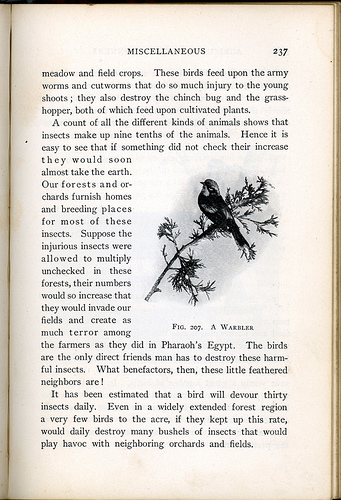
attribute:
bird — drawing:
[196, 175, 246, 250]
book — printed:
[2, 2, 337, 495]